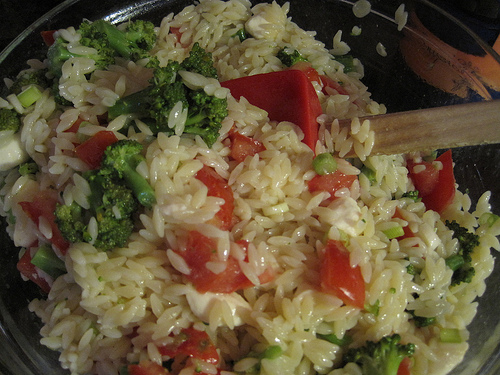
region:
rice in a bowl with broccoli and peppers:
[42, 42, 393, 351]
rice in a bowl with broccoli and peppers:
[71, 193, 340, 351]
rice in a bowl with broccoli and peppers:
[112, 18, 264, 165]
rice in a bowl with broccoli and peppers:
[353, 223, 490, 344]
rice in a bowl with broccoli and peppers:
[282, 270, 434, 361]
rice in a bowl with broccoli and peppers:
[106, 295, 201, 331]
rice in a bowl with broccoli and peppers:
[233, 105, 388, 247]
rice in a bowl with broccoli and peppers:
[142, 5, 363, 97]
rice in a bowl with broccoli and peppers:
[38, 96, 185, 241]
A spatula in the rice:
[220, 70, 497, 172]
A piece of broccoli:
[348, 333, 410, 373]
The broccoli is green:
[348, 333, 413, 374]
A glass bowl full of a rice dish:
[3, 2, 498, 374]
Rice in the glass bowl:
[0, 3, 498, 372]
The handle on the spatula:
[325, 102, 497, 164]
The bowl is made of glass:
[0, 0, 498, 373]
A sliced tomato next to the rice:
[318, 242, 363, 304]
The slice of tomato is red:
[323, 244, 365, 304]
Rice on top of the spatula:
[316, 116, 373, 158]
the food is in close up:
[4, 11, 491, 372]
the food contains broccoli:
[80, 145, 150, 240]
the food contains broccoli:
[120, 70, 217, 140]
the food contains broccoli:
[356, 334, 408, 374]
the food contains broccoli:
[81, 24, 147, 63]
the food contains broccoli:
[28, 41, 85, 89]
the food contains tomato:
[316, 231, 373, 310]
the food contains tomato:
[255, 70, 333, 146]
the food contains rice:
[25, 26, 490, 368]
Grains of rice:
[262, 176, 300, 219]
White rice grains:
[246, 179, 294, 212]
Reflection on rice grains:
[253, 171, 292, 206]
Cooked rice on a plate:
[253, 178, 297, 235]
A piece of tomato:
[235, 138, 247, 153]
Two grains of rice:
[396, 6, 407, 27]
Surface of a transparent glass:
[395, 81, 417, 102]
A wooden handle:
[443, 116, 486, 133]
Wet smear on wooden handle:
[386, 125, 414, 137]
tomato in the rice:
[161, 222, 253, 301]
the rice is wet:
[261, 298, 316, 352]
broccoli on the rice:
[49, 183, 153, 257]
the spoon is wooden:
[340, 99, 495, 147]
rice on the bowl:
[265, 142, 285, 194]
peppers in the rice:
[222, 322, 282, 357]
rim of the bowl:
[371, 38, 468, 97]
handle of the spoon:
[351, 102, 461, 152]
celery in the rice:
[9, 83, 53, 109]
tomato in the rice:
[216, 62, 325, 146]